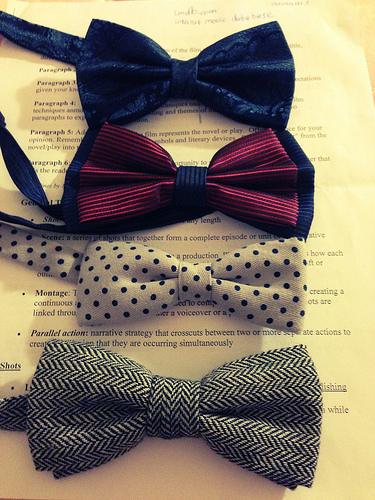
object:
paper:
[5, 2, 373, 495]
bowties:
[4, 5, 365, 491]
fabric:
[25, 22, 68, 57]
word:
[30, 327, 62, 336]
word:
[33, 287, 68, 297]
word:
[28, 128, 66, 135]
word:
[317, 153, 331, 162]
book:
[1, 0, 372, 499]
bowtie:
[2, 7, 300, 129]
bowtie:
[1, 116, 319, 241]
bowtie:
[0, 222, 310, 343]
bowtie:
[5, 332, 331, 493]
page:
[1, 1, 373, 499]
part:
[316, 5, 373, 100]